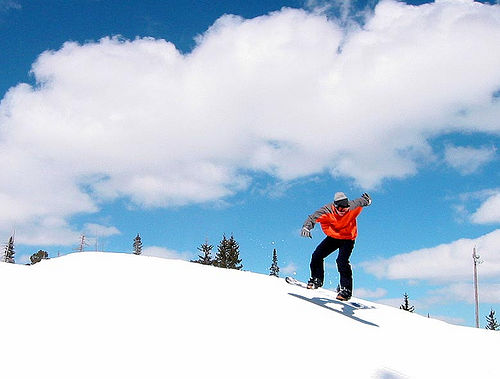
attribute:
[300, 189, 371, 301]
man — jumping, enjoying, airborn, snowboarding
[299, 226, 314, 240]
glove — grey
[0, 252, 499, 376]
ground — snowy, white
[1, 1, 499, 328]
sky — blue, bright, cloudy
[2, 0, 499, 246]
cloud — white, big, fluffy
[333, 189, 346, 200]
hat — grey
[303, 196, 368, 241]
coat — gray, orange, red, grey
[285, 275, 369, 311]
snowboard — white, grey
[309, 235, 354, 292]
pants — black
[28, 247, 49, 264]
tree — green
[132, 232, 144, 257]
tree — green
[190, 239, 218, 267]
tree — green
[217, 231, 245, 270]
tree — green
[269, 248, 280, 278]
tree — green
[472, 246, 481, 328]
pole — wood